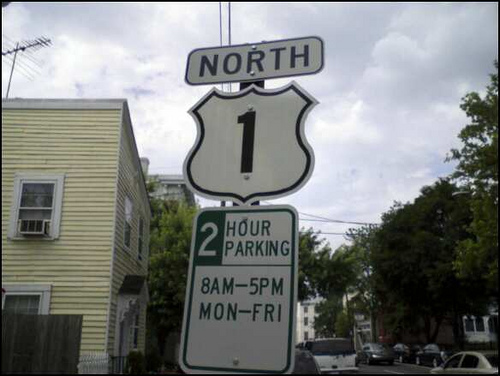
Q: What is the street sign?
A: Black and white.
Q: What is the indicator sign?
A: Route one.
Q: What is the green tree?
A: Small.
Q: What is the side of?
A: House.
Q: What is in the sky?
A: Clouds.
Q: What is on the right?
A: Roadway.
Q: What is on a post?
A: Signs.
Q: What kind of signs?
A: Road.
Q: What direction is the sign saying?
A: North.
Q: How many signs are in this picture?
A: Three.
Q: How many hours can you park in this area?
A: Two hours.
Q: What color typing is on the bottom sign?
A: Green.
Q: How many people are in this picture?
A: Zero.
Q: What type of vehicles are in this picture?
A: Cars.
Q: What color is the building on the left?
A: Yellow.